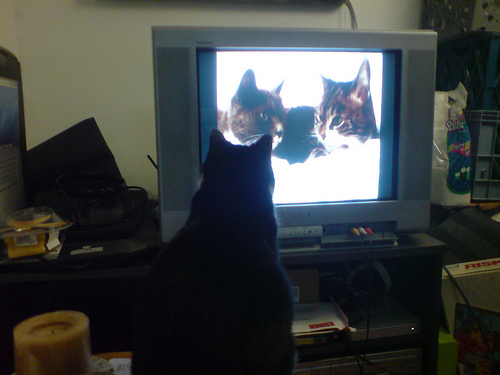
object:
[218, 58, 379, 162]
cats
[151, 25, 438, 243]
tv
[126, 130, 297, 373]
cat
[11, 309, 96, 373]
candle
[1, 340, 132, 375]
table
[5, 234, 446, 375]
stand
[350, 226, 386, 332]
cords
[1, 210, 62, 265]
dvd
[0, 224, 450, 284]
shelf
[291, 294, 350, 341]
papers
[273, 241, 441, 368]
shelf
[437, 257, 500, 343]
box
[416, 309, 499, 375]
floor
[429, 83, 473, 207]
bag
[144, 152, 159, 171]
cord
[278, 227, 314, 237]
knobs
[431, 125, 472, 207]
toilet paper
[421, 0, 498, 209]
crates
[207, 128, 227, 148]
ear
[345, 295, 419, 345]
dvd player